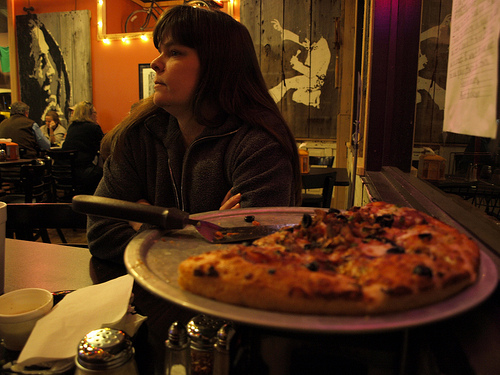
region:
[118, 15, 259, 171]
this is a lady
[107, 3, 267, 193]
the lady is sitted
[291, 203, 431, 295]
this is a pizza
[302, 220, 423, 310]
the pizza is big in size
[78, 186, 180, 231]
this is the handle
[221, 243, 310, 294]
the pizza is fat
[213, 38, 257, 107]
this is the hair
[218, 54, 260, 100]
the hair is long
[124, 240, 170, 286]
this is a tray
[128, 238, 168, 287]
the tray is flat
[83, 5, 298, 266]
woman in a black coat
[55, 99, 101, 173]
blonde woman sitting at the table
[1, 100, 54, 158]
man in a gray vest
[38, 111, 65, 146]
woman in a white jacket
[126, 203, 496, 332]
half a pizza on the tray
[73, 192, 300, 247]
metal spatula on the tray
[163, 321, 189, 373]
salt shaker on the table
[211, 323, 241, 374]
pepper shaker on the table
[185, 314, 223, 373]
chili peppers on the table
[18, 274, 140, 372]
white folded up napikin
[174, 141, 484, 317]
a pizza on a pizza pan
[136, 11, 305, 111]
the head of a woman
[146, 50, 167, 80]
the nose of a woman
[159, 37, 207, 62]
the eye of a woman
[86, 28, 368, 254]
a woman in front of a pizza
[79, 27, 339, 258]
a woman wearing a jacket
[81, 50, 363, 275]
a woman with a jacket on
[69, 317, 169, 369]
a salt shaker on a table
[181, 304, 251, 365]
a pepper shaker on a table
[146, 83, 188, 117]
the chin of a woman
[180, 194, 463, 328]
half of a pizza on a metal platter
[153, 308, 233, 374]
salt, pepper, and red pepper shakers on the table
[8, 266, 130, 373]
white cloth napkin on the table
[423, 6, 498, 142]
a white paper on the window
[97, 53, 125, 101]
orange wall of the restaurant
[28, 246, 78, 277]
black surface of the table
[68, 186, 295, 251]
a serving spatula on a metal pan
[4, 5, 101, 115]
a painting of a man on a grey wood base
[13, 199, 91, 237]
black wood back of a chair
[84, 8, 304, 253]
a woman wearing a black fleece jacket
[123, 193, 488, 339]
Half of a pizza on a tray.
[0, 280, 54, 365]
White styrofoam cup near napkins.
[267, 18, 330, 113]
Drawing of Elvis in white.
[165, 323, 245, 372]
Salt and peppers on a table.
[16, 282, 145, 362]
White napkins near cup.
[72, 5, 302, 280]
Woman with her arms crossed.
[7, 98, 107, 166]
Three people sitting at a table.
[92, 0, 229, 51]
Bike surrounded by lights.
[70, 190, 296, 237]
Metal and black pie server.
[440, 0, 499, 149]
White piece of paper hanging on window.